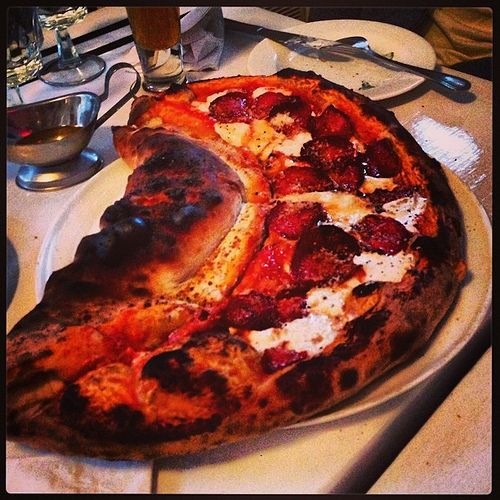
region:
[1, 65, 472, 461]
the pizza is burnt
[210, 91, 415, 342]
pepperonis on the pizza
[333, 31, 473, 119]
spoon on the plate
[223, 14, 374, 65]
knife on the plate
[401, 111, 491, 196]
light reflecting on table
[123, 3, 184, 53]
brown liquid in cup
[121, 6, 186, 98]
cup made of glass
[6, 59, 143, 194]
cup made of metal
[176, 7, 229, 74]
napkin behind the cup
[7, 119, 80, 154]
brown liquid in cup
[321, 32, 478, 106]
fork on the plate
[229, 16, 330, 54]
butter knife on the plate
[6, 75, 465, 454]
pizza on the plate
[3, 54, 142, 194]
gravy boat on the table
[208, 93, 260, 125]
pepperoni on the plate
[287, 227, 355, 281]
pepperoni on the pizza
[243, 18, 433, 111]
plate on the table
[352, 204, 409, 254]
pepperoni on the cheese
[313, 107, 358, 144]
pepperoni on the pizza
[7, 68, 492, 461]
pizza on the white plate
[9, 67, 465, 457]
large round pepperoni pizza bent in middle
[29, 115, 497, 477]
round white plate with pizza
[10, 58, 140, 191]
silver ladle on table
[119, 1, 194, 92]
tall glass of light beer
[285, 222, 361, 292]
piece of chargrilled pepperoni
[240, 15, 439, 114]
small round white plate with utensils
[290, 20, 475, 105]
silver fork and knife on plate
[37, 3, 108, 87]
wine glass next to beer glass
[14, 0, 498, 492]
indoor restaurant scene with deep dish pizza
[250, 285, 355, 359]
lump of white melted mozzarella cheese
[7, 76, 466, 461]
Pizza on the plate.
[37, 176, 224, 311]
Burnt pizza crust.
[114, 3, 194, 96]
Glass on the table.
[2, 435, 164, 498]
White napkin on the table.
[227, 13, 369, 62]
Knife on the plate.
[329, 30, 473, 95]
Fork on the plate.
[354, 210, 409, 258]
Pepperoni on the pizza.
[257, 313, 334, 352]
melted cheese on the pizza.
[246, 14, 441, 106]
White plate on the table.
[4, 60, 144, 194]
Silver colored serving dish.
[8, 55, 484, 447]
a burnt disfigured pizza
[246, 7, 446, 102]
an empty white plate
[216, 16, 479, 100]
utensils on the white plate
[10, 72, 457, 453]
pizza with burnt crust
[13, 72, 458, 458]
pizza with pepperoni toppings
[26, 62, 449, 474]
cheese pizza with pepperoni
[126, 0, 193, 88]
glass with beer inside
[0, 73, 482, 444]
a burnt pizza that's not cicular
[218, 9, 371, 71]
knife atop the white plate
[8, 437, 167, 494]
white napkins next to pizza